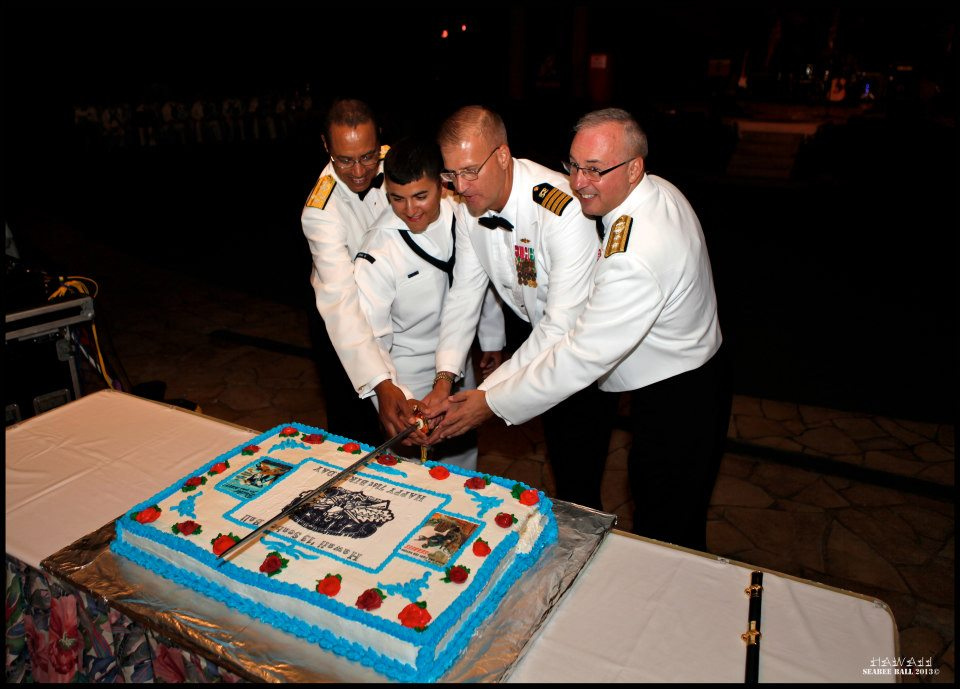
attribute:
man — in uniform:
[428, 99, 602, 407]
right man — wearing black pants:
[481, 104, 728, 556]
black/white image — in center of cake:
[290, 478, 398, 539]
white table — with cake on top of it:
[4, 377, 902, 684]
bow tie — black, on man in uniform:
[472, 212, 512, 234]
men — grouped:
[287, 89, 767, 534]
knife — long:
[205, 382, 465, 570]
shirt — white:
[292, 173, 396, 403]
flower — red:
[392, 595, 440, 635]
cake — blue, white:
[98, 405, 595, 684]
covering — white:
[13, 380, 910, 685]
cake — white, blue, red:
[107, 413, 567, 680]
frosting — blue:
[112, 413, 569, 680]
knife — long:
[212, 411, 437, 569]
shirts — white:
[302, 146, 420, 418]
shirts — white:
[342, 181, 521, 413]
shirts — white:
[418, 136, 632, 424]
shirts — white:
[475, 176, 747, 437]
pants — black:
[606, 335, 756, 558]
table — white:
[7, 375, 914, 685]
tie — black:
[395, 214, 478, 292]